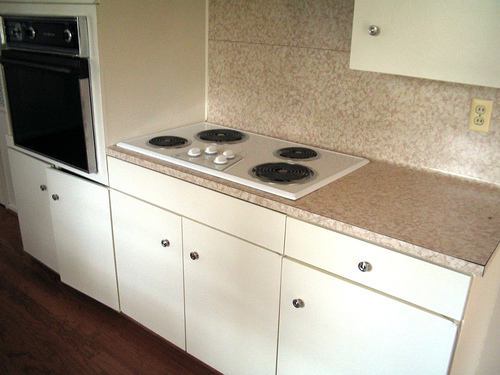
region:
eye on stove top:
[258, 155, 305, 190]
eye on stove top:
[285, 138, 319, 163]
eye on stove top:
[208, 121, 251, 148]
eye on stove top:
[149, 127, 190, 148]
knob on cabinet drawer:
[350, 260, 372, 272]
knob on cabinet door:
[285, 295, 308, 310]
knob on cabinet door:
[188, 247, 198, 259]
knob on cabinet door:
[152, 234, 170, 253]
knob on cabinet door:
[362, 22, 386, 41]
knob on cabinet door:
[44, 190, 65, 207]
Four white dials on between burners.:
[175, 141, 240, 171]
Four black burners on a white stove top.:
[146, 126, 322, 186]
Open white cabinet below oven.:
[41, 156, 111, 291]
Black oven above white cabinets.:
[0, 1, 106, 172]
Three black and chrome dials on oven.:
[0, 16, 81, 44]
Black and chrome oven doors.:
[0, 50, 100, 175]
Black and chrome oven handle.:
[0, 52, 80, 77]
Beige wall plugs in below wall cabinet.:
[463, 91, 490, 139]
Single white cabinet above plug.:
[346, 0, 497, 75]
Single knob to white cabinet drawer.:
[354, 251, 374, 278]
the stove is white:
[157, 86, 253, 181]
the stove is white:
[120, 71, 351, 361]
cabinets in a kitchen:
[38, 180, 450, 362]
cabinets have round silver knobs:
[272, 280, 321, 330]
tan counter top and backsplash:
[349, 125, 476, 279]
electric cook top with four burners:
[132, 108, 319, 193]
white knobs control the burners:
[181, 139, 242, 171]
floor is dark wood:
[29, 300, 108, 363]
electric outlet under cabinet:
[456, 88, 489, 143]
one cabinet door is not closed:
[18, 146, 126, 316]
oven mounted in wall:
[9, 0, 119, 200]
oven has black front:
[27, 45, 79, 147]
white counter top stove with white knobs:
[116, 108, 383, 198]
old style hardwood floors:
[2, 200, 215, 374]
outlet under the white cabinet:
[466, 99, 492, 129]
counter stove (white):
[124, 89, 381, 205]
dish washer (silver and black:
[0, 8, 102, 175]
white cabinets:
[53, 217, 383, 345]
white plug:
[463, 95, 495, 132]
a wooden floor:
[28, 286, 160, 356]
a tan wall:
[104, 14, 182, 120]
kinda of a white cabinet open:
[29, 162, 99, 242]